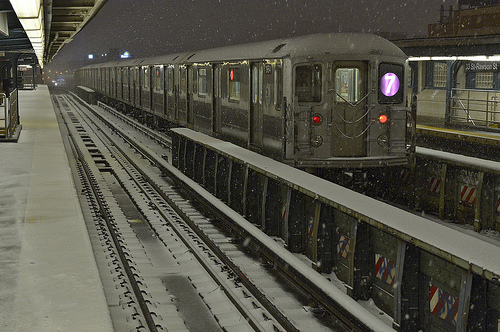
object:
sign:
[335, 232, 356, 262]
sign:
[456, 182, 478, 205]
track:
[51, 85, 293, 331]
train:
[74, 30, 418, 169]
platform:
[0, 82, 116, 330]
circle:
[379, 73, 401, 97]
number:
[386, 75, 398, 95]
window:
[432, 59, 452, 87]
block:
[434, 71, 440, 77]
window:
[473, 69, 494, 90]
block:
[477, 74, 480, 80]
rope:
[330, 88, 374, 108]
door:
[332, 60, 371, 157]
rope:
[333, 104, 374, 125]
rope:
[334, 119, 372, 138]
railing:
[446, 87, 499, 129]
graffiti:
[439, 288, 461, 323]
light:
[310, 114, 324, 127]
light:
[378, 115, 390, 127]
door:
[250, 60, 267, 150]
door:
[212, 62, 225, 136]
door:
[164, 64, 169, 125]